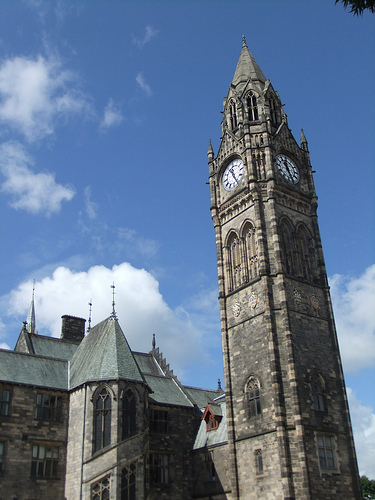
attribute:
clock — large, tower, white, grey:
[213, 134, 256, 201]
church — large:
[2, 272, 184, 477]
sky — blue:
[62, 57, 149, 163]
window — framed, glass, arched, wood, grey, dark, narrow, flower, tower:
[226, 224, 255, 264]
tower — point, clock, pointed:
[150, 8, 313, 317]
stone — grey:
[37, 402, 104, 474]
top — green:
[177, 41, 273, 136]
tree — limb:
[326, 9, 374, 24]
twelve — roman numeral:
[224, 151, 243, 169]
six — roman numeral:
[223, 177, 240, 199]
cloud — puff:
[119, 50, 211, 113]